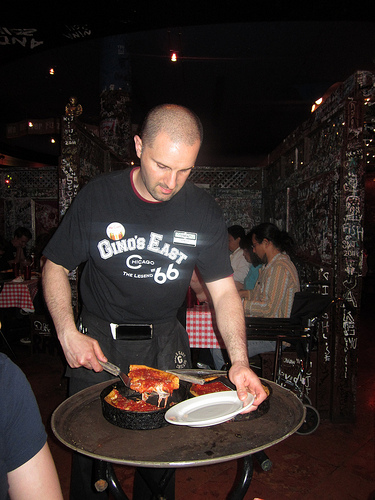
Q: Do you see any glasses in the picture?
A: No, there are no glasses.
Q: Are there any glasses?
A: No, there are no glasses.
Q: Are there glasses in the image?
A: No, there are no glasses.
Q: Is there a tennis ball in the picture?
A: No, there are no tennis balls.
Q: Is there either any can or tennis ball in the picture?
A: No, there are no tennis balls or cans.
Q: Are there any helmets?
A: No, there are no helmets.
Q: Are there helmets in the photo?
A: No, there are no helmets.